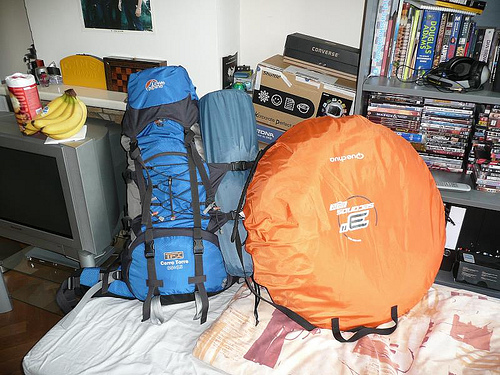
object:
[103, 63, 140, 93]
chess board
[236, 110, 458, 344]
orange bag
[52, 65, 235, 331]
blue backpack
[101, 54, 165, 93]
checker set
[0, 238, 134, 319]
table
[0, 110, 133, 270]
television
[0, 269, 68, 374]
ground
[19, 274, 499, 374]
bed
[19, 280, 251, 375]
sheet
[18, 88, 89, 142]
bunch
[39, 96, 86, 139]
bananas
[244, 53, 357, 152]
box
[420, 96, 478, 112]
dvds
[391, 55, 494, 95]
headphones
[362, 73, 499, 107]
shelf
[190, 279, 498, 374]
pillow case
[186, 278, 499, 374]
design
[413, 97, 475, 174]
dvd stack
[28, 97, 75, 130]
bananas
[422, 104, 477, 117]
dvds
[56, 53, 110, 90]
brown chair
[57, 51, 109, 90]
chair back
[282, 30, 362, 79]
shoe box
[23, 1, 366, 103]
wall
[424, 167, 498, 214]
shelf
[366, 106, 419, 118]
dvd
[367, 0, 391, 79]
books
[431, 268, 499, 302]
shelf